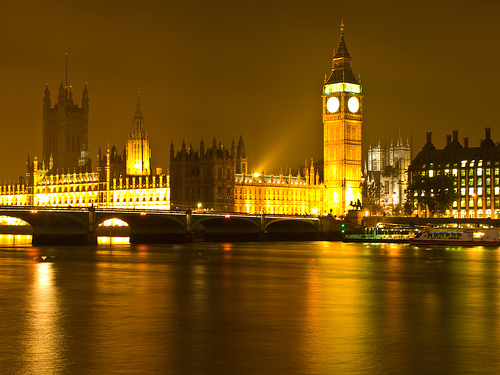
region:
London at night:
[37, 10, 462, 310]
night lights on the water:
[22, 256, 413, 362]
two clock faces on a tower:
[320, 82, 360, 117]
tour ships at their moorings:
[340, 210, 492, 255]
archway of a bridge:
[90, 210, 185, 245]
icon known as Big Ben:
[311, 15, 366, 210]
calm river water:
[91, 316, 292, 366]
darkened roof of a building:
[410, 120, 495, 155]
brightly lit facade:
[265, 160, 320, 210]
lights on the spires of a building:
[37, 45, 92, 111]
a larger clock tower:
[323, 20, 369, 208]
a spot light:
[250, 169, 264, 185]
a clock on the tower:
[350, 93, 358, 113]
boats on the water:
[406, 227, 488, 243]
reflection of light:
[234, 249, 379, 354]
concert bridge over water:
[0, 205, 337, 247]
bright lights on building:
[25, 173, 178, 205]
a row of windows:
[462, 175, 497, 188]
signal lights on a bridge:
[24, 209, 47, 218]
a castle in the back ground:
[367, 126, 408, 208]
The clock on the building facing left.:
[330, 93, 338, 113]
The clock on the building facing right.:
[345, 95, 359, 113]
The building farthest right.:
[412, 129, 497, 221]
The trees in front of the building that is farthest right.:
[415, 168, 461, 221]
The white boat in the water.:
[335, 219, 420, 240]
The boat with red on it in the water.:
[407, 225, 499, 252]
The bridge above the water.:
[4, 188, 497, 235]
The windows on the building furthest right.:
[419, 166, 499, 217]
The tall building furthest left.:
[26, 43, 100, 165]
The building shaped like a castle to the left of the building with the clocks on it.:
[1, 130, 321, 208]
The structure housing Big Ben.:
[318, 23, 371, 217]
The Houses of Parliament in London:
[43, 56, 378, 248]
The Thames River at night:
[123, 246, 390, 373]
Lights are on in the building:
[413, 134, 497, 227]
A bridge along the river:
[13, 199, 318, 266]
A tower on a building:
[44, 75, 95, 170]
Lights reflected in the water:
[325, 240, 457, 266]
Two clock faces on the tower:
[326, 95, 364, 113]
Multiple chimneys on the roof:
[421, 129, 498, 153]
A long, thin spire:
[62, 50, 72, 84]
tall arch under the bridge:
[75, 203, 144, 264]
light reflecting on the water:
[262, 263, 387, 318]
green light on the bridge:
[331, 215, 354, 235]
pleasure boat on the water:
[326, 222, 473, 248]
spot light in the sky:
[238, 133, 309, 191]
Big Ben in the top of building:
[311, 93, 371, 118]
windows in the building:
[448, 163, 493, 212]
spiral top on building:
[181, 129, 256, 165]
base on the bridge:
[242, 214, 284, 244]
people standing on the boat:
[361, 219, 416, 236]